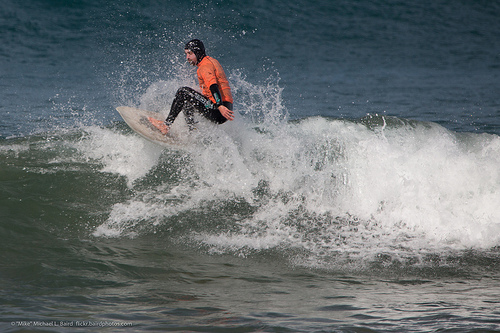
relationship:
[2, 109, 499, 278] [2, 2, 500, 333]
wave inside of ocean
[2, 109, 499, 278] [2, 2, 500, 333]
wave in ocean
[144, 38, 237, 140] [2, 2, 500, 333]
man surfboarding on ocean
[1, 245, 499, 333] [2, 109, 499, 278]
water in front of wave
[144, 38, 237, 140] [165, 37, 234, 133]
man wearing wet suit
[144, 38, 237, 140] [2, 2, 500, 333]
man surfing in ocean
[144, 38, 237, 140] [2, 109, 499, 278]
man surfing a wave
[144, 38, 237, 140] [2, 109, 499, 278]
man surfing wave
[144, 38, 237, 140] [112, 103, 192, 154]
man on top of surfboard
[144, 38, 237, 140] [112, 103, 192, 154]
man riding surfboard